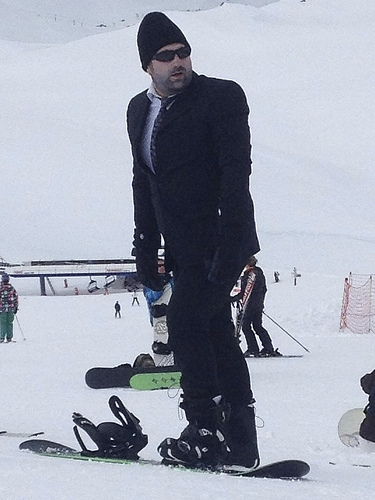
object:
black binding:
[72, 395, 149, 461]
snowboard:
[85, 354, 183, 391]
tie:
[149, 92, 179, 175]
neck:
[152, 76, 178, 98]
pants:
[0, 310, 15, 339]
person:
[0, 273, 18, 343]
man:
[232, 255, 275, 358]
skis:
[244, 348, 304, 358]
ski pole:
[262, 310, 311, 353]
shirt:
[139, 81, 181, 175]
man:
[126, 10, 261, 475]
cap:
[136, 10, 190, 73]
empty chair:
[87, 279, 101, 293]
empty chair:
[103, 274, 115, 288]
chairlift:
[0, 258, 137, 296]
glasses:
[151, 44, 191, 62]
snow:
[303, 379, 330, 396]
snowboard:
[18, 394, 310, 481]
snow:
[0, 354, 58, 417]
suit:
[126, 68, 261, 410]